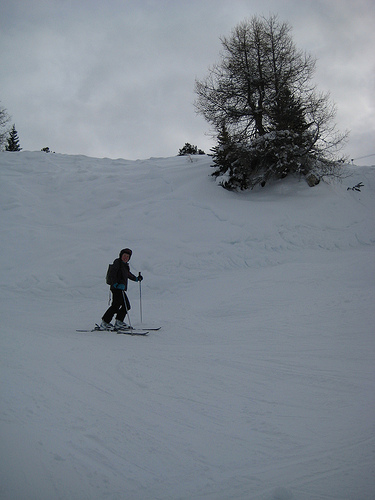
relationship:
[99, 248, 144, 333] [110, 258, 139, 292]
boy has jacket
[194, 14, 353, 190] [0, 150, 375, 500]
tree in snow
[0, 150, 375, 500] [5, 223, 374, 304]
snow has tracks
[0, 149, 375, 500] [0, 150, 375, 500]
hill has snow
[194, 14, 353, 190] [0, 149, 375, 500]
tree on hill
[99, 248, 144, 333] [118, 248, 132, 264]
boy has head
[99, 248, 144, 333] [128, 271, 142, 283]
boy has arm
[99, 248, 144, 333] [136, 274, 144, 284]
boy has hand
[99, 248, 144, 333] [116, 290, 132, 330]
boy has leg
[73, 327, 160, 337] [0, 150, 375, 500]
ski in snow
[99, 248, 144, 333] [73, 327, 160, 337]
boy on ski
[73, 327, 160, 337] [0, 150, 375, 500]
ski by snow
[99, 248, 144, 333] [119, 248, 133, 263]
boy wearing hat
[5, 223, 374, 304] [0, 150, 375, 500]
tracks in snow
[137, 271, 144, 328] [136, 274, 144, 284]
pole in hand